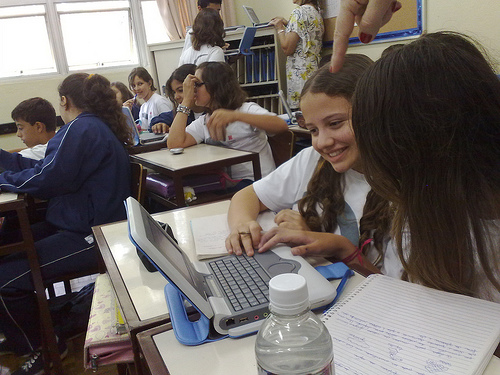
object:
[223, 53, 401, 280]
girl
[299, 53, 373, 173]
head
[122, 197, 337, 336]
tv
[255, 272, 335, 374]
bottle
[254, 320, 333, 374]
water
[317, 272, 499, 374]
notebook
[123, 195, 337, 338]
laptop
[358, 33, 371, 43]
fingernails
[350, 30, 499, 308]
girls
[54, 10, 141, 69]
windows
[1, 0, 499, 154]
wall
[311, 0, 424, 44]
corkboard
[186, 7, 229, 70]
people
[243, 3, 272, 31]
laptops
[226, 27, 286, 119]
bookshelf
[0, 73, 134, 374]
students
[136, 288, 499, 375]
desks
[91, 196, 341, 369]
table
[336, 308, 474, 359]
writing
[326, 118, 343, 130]
eye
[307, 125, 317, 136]
eye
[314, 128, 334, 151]
nose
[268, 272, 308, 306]
lid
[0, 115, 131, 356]
tracksuit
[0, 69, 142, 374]
girl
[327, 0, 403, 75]
hand